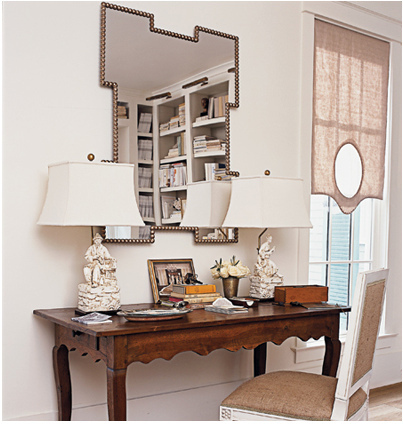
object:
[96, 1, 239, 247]
mirror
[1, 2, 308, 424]
wall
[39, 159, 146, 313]
lamp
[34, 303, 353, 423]
table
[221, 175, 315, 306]
lamp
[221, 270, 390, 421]
chair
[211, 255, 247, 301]
vase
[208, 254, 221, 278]
flowers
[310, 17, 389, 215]
curtain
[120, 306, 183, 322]
plate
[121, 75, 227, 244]
reflection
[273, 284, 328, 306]
box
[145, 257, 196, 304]
picture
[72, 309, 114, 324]
notepad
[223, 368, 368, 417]
seat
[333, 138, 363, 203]
keyhole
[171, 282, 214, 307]
stack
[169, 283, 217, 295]
books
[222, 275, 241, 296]
bucket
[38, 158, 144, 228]
lampshade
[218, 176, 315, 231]
lampshade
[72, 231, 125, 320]
sculpture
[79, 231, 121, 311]
base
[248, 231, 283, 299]
sculpture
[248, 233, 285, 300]
base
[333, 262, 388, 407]
backrest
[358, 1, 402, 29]
ceiling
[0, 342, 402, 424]
floor boards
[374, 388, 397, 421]
floor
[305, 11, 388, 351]
window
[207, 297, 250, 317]
book